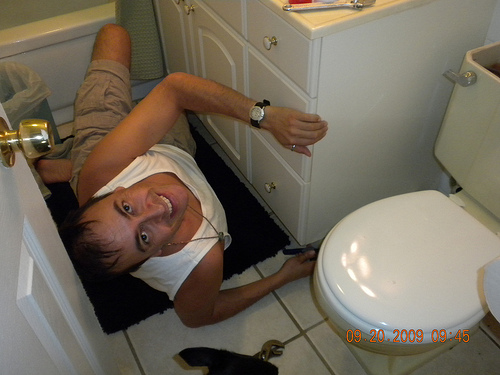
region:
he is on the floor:
[182, 160, 238, 210]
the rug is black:
[111, 287, 139, 307]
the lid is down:
[359, 222, 405, 273]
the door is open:
[1, 109, 78, 254]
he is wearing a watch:
[246, 98, 268, 131]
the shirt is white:
[166, 152, 200, 179]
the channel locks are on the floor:
[256, 334, 286, 363]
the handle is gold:
[8, 116, 58, 158]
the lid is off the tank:
[466, 39, 498, 84]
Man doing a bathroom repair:
[0, 1, 497, 373]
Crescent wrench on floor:
[254, 341, 284, 358]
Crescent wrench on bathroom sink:
[283, 0, 373, 11]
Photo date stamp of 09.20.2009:
[343, 328, 425, 343]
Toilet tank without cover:
[433, 38, 498, 224]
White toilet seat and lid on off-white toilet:
[313, 42, 496, 372]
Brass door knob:
[0, 120, 57, 166]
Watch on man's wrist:
[247, 99, 271, 126]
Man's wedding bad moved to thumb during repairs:
[282, 141, 309, 156]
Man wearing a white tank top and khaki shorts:
[67, 56, 231, 300]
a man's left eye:
[119, 199, 134, 215]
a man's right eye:
[135, 229, 151, 248]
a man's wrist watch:
[249, 100, 269, 130]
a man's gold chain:
[167, 203, 224, 248]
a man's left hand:
[265, 102, 330, 157]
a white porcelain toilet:
[310, 43, 498, 374]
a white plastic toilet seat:
[318, 192, 499, 342]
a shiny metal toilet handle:
[444, 68, 478, 89]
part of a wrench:
[258, 338, 284, 360]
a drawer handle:
[260, 37, 277, 52]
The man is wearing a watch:
[249, 99, 267, 126]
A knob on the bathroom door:
[1, 119, 53, 164]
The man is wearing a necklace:
[168, 204, 223, 244]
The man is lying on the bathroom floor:
[38, 27, 326, 328]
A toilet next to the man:
[312, 41, 497, 364]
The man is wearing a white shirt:
[90, 143, 228, 299]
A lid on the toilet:
[319, 190, 498, 332]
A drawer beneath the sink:
[243, 4, 320, 96]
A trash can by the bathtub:
[0, 60, 57, 140]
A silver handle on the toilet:
[445, 68, 473, 86]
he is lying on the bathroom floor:
[32, 35, 339, 325]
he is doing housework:
[53, 15, 356, 332]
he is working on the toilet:
[63, 25, 430, 347]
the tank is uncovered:
[456, 30, 496, 72]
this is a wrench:
[245, 333, 310, 368]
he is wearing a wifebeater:
[65, 93, 258, 312]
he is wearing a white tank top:
[60, 52, 317, 353]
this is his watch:
[242, 75, 274, 145]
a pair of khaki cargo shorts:
[59, 34, 198, 165]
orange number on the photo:
[343, 325, 354, 345]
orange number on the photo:
[350, 323, 357, 343]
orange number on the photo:
[367, 326, 374, 342]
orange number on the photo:
[376, 327, 382, 342]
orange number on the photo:
[391, 325, 401, 345]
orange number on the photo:
[400, 327, 410, 343]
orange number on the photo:
[405, 325, 413, 342]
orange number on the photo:
[416, 327, 422, 342]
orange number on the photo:
[430, 326, 437, 342]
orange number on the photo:
[437, 326, 447, 343]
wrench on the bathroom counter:
[281, 0, 374, 17]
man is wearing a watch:
[246, 96, 272, 130]